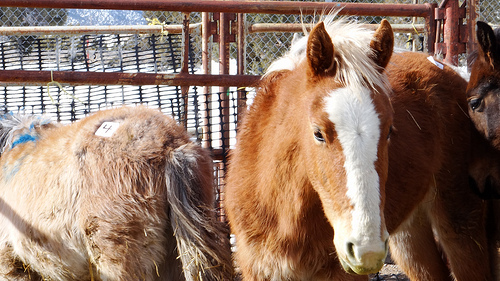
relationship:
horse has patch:
[226, 17, 498, 278] [323, 85, 385, 256]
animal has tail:
[2, 100, 222, 279] [162, 138, 219, 277]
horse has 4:
[226, 17, 498, 278] [102, 124, 112, 134]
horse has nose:
[226, 17, 499, 281] [306, 164, 410, 279]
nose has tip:
[306, 164, 410, 279] [350, 242, 416, 278]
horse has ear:
[226, 17, 499, 281] [368, 8, 415, 81]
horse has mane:
[226, 17, 499, 281] [303, 8, 399, 94]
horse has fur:
[226, 17, 499, 281] [17, 124, 210, 259]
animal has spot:
[0, 100, 223, 281] [7, 131, 37, 149]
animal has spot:
[0, 100, 223, 281] [28, 116, 52, 128]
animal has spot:
[0, 100, 223, 281] [6, 154, 27, 176]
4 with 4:
[102, 124, 112, 134] [98, 120, 112, 135]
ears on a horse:
[298, 11, 401, 83] [208, 49, 449, 276]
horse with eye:
[226, 17, 498, 278] [311, 127, 328, 143]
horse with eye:
[226, 17, 498, 278] [388, 122, 394, 139]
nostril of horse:
[341, 237, 365, 269] [210, 4, 492, 279]